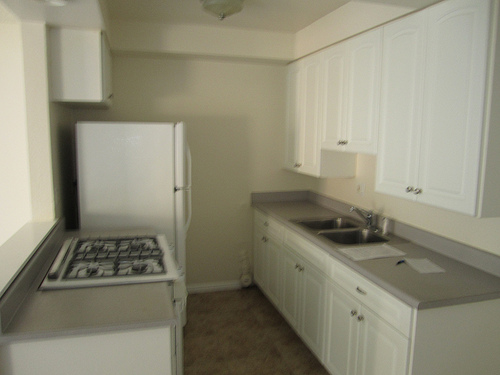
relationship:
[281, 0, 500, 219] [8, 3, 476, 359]
cabinets in kitchen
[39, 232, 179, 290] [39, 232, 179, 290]
burners with burners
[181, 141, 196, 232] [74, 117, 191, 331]
handle on efridgerator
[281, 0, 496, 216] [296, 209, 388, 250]
cabinets over sink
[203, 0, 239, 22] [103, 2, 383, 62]
lamp in ceiling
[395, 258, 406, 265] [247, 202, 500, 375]
pen on counter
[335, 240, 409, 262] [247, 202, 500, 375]
paper on counter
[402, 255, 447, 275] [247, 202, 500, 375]
paper on counter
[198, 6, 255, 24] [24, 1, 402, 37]
light hanging from ceiling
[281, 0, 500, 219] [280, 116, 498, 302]
cabinets on wall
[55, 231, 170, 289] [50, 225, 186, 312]
burners on stove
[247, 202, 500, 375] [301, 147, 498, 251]
counter against wall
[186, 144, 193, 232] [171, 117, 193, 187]
handle on freezer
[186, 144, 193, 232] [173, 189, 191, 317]
handle on fridge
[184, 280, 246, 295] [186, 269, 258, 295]
molding on wall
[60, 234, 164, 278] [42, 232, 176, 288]
range on stove